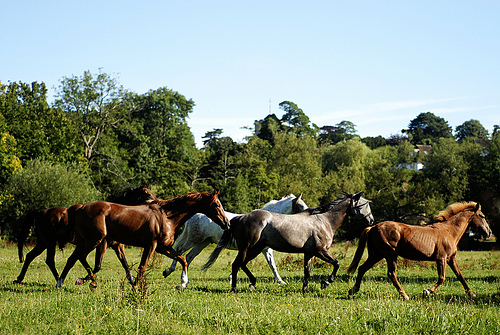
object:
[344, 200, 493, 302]
horse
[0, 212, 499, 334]
field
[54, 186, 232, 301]
horse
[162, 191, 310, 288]
horse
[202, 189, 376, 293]
horse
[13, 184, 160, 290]
horse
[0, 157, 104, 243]
tree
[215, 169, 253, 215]
tree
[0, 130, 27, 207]
tree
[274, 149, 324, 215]
tree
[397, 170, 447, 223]
tree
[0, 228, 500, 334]
grass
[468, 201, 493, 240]
head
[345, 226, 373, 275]
tail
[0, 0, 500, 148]
sky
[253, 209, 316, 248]
sheen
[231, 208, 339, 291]
body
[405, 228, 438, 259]
ribs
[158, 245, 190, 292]
leg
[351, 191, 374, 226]
head covering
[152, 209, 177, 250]
muscles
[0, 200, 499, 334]
group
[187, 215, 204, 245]
spots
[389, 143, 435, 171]
house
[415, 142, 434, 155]
roof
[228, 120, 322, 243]
trees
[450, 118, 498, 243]
row of trees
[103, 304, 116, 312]
flower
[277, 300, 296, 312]
flower